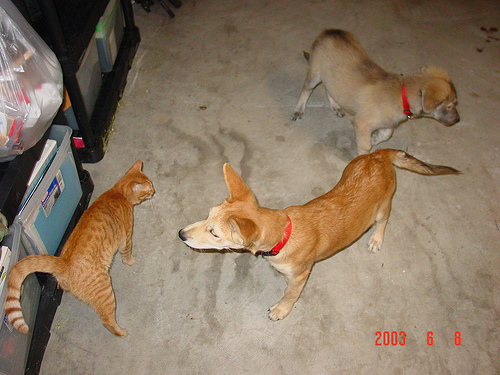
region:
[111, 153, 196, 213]
head of a cat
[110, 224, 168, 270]
leg of a cat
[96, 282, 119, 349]
leg of a cat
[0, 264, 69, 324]
tail of a cat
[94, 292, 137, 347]
a leg of a cat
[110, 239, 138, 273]
a leg of a cat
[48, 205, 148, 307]
body of a cat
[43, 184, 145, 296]
a body of a cat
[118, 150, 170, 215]
a head of a cat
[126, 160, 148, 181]
an ear of a cat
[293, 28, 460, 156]
a bown dog standing on a carpet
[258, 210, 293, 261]
a dog wearing a red and black collar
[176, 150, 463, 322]
a chihuahua looking at a cat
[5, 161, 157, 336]
an orange tabby cat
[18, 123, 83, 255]
a plastic container on a bottom shelf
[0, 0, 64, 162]
a plastic bag on a black shelf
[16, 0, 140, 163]
a black bookshelf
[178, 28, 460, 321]
two brown dogs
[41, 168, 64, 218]
a sticker on a plastic container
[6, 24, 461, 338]
two brown dogs and an orange cat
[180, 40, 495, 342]
two dogs are on the floor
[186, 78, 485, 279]
both dogs have neckcolllars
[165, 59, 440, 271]
their neck collars are same in color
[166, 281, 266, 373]
the floor is gray in color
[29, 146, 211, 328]
a cat is next to the dog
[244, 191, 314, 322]
neckcollar is red in color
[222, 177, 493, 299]
dog is brown in color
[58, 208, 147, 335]
cat is brown in color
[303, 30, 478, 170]
dog is gray in color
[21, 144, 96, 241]
the tray is light blue in color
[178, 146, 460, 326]
the dog on the gorund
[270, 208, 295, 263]
the red collar on the dog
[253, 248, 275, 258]
the balck clip on the red collar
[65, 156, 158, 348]
the orange stripped cat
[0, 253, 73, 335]
the orange tail of the cat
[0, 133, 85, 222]
the plastic crate in the corner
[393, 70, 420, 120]
the collar on the dogs neck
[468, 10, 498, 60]
the oil drips on the ground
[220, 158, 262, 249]
the ears on the head of the dog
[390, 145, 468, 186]
the tail of the dog sticking out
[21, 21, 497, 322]
The animals are inside a house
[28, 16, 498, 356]
The animals are a cat and some dogs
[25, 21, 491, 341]
The dogs are making the cat nervous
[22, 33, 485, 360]
The cat is watching the dogs closely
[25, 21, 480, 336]
The dogs are interested in the cat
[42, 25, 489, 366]
The animals are waiting to be fed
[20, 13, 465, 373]
The animals are waiting for their master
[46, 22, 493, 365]
The animals are getting along nicely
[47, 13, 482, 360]
The animals are having a great time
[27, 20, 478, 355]
The animals are enjoying the day